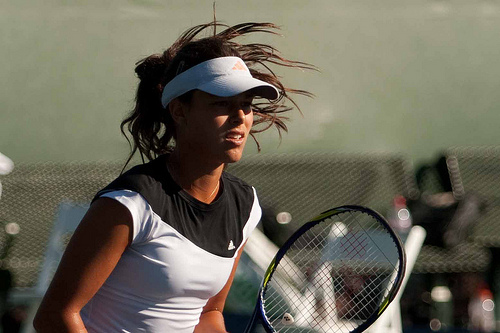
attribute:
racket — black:
[246, 200, 405, 331]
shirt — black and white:
[79, 154, 263, 331]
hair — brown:
[100, 13, 288, 75]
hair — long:
[113, 16, 320, 181]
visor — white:
[163, 55, 278, 110]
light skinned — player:
[197, 109, 219, 131]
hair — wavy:
[128, 23, 318, 92]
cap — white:
[160, 55, 277, 102]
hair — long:
[124, 26, 286, 161]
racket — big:
[236, 167, 431, 309]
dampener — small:
[277, 281, 327, 321]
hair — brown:
[127, 22, 293, 128]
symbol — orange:
[226, 57, 257, 78]